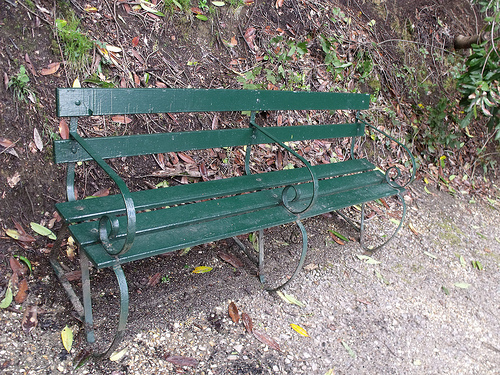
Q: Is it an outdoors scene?
A: Yes, it is outdoors.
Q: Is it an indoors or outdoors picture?
A: It is outdoors.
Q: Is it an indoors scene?
A: No, it is outdoors.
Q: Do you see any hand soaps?
A: No, there are no hand soaps.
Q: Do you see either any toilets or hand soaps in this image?
A: No, there are no hand soaps or toilets.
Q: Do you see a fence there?
A: No, there are no fences.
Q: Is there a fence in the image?
A: No, there are no fences.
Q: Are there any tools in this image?
A: No, there are no tools.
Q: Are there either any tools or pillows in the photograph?
A: No, there are no tools or pillows.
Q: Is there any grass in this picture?
A: Yes, there is grass.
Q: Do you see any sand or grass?
A: Yes, there is grass.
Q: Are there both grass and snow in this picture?
A: No, there is grass but no snow.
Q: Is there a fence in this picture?
A: No, there are no fences.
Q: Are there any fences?
A: No, there are no fences.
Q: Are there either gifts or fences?
A: No, there are no fences or gifts.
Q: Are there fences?
A: No, there are no fences.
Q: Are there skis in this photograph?
A: No, there are no skis.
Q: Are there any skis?
A: No, there are no skis.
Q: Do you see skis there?
A: No, there are no skis.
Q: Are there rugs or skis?
A: No, there are no skis or rugs.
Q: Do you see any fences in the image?
A: No, there are no fences.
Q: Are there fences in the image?
A: No, there are no fences.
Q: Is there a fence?
A: No, there are no fences.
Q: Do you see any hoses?
A: No, there are no hoses.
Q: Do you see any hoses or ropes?
A: No, there are no hoses or ropes.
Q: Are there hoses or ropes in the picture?
A: No, there are no hoses or ropes.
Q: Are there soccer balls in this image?
A: No, there are no soccer balls.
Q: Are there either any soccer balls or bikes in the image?
A: No, there are no soccer balls or bikes.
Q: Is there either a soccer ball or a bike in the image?
A: No, there are no soccer balls or bikes.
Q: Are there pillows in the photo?
A: No, there are no pillows.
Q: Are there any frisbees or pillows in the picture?
A: No, there are no pillows or frisbees.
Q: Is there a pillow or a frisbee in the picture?
A: No, there are no pillows or frisbees.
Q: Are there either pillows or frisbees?
A: No, there are no pillows or frisbees.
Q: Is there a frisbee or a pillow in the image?
A: No, there are no pillows or frisbees.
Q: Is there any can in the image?
A: No, there are no cans.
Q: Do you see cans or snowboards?
A: No, there are no cans or snowboards.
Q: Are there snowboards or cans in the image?
A: No, there are no cans or snowboards.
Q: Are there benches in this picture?
A: Yes, there is a bench.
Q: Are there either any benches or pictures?
A: Yes, there is a bench.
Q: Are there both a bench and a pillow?
A: No, there is a bench but no pillows.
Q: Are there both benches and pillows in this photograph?
A: No, there is a bench but no pillows.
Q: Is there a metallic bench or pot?
A: Yes, there is a metal bench.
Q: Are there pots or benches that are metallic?
A: Yes, the bench is metallic.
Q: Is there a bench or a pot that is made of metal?
A: Yes, the bench is made of metal.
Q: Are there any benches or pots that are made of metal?
A: Yes, the bench is made of metal.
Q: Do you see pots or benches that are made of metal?
A: Yes, the bench is made of metal.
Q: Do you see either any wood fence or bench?
A: Yes, there is a wood bench.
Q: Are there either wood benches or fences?
A: Yes, there is a wood bench.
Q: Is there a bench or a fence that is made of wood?
A: Yes, the bench is made of wood.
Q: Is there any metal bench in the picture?
A: Yes, there is a metal bench.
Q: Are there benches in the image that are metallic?
A: Yes, there is a bench that is metallic.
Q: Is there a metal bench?
A: Yes, there is a bench that is made of metal.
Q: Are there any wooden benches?
A: Yes, there is a wood bench.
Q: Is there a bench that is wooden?
A: Yes, there is a bench that is wooden.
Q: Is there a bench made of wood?
A: Yes, there is a bench that is made of wood.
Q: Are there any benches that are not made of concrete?
A: Yes, there is a bench that is made of wood.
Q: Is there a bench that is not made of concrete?
A: Yes, there is a bench that is made of wood.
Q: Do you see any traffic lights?
A: No, there are no traffic lights.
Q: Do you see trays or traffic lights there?
A: No, there are no traffic lights or trays.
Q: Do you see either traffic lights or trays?
A: No, there are no traffic lights or trays.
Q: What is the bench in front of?
A: The bench is in front of the leaf.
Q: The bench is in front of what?
A: The bench is in front of the leaf.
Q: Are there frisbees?
A: No, there are no frisbees.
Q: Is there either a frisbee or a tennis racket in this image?
A: No, there are no frisbees or rackets.